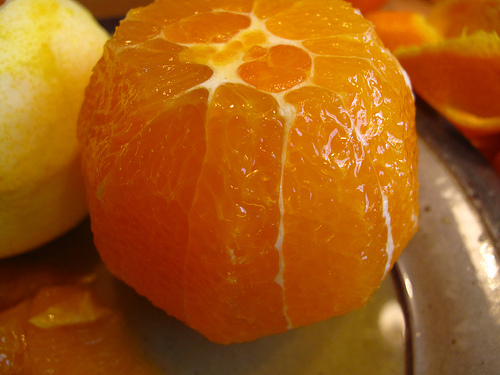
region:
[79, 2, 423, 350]
peeled orange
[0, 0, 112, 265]
zested orange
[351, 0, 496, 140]
orange slices in the background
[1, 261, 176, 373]
oranges under the main focus orange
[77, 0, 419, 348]
a peeled juicy orange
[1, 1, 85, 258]
an orange with the white flesh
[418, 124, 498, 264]
brown trim on the plate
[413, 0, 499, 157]
the discarded peeled orange skin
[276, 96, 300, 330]
white flesh veins of the orange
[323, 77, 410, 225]
light reflection on the wet juice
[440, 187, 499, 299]
light reflecting off of the plate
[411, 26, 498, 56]
white flesh on the inside of the orange skin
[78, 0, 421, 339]
A peeled orange on a plate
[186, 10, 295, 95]
Pith on an orange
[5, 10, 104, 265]
Orange with pith still on it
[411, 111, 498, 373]
Edge of a plate under oranges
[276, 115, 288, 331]
A line of pith on an orange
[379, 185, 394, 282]
Pith on an orange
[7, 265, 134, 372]
Reflection of oranges on a plate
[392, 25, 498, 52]
Pith on the edge of an orange piece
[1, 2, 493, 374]
Oranges resting on a shiny plate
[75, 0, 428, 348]
A peeled orange.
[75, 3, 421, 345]
An orange that has been peeled.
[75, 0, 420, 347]
An orange that has no skin.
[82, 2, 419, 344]
A wet looking peeled orange.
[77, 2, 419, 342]
An orange orange that has been peeled.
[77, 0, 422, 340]
Peeled orange that is orange and white.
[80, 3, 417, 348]
A shiny orange colored orange.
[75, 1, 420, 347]
Orange with no skin.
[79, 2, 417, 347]
Peeled orange that appears wet with white lines in it.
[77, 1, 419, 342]
Oval shaped peeled orange.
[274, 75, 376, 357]
a slice of orange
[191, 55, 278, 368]
a slice of orange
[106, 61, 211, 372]
a slice of orange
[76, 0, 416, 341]
peeled orange is juicy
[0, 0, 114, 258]
orange is next to orange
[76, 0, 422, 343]
orange is next to orange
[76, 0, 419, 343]
orange on top of silver tray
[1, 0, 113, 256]
orange on top of silver tray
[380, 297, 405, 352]
reflection of light on tray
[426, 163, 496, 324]
reflection of light on tray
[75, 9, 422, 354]
a peeled orange on a plate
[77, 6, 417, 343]
an orange without it's rind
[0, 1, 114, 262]
An orange with it's healthy pith on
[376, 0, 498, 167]
pile of orange peelings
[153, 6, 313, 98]
the top of the smaller inner orange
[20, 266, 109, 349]
reflection of the orange on the plate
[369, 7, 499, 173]
the porous rind with pith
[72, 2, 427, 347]
Orange on the plate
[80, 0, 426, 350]
peeled orange on the plate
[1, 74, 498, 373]
silver plate under the orange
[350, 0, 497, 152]
orange peels in the background